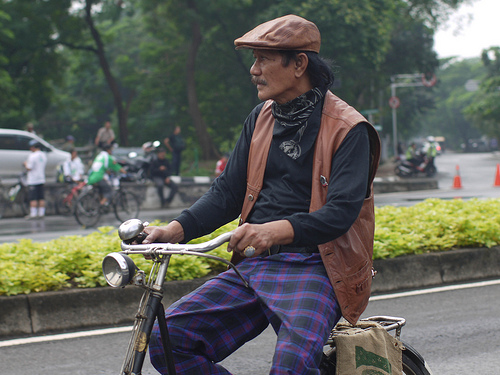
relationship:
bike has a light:
[89, 228, 417, 373] [101, 252, 135, 291]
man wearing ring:
[132, 10, 394, 374] [244, 242, 256, 257]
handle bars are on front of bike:
[116, 217, 241, 260] [89, 228, 417, 373]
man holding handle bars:
[132, 10, 394, 374] [116, 217, 241, 260]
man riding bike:
[132, 10, 394, 374] [89, 228, 417, 373]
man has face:
[132, 10, 394, 374] [246, 49, 280, 98]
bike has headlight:
[89, 228, 417, 373] [94, 251, 144, 290]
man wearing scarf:
[132, 10, 394, 374] [265, 83, 322, 162]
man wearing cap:
[132, 10, 394, 374] [236, 18, 320, 57]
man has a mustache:
[132, 10, 394, 374] [248, 77, 269, 88]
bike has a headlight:
[89, 228, 417, 373] [94, 251, 144, 290]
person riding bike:
[90, 139, 126, 204] [30, 133, 93, 175]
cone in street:
[447, 158, 464, 191] [421, 136, 500, 206]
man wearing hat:
[132, 10, 394, 374] [230, 10, 333, 58]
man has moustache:
[132, 10, 394, 374] [248, 71, 270, 86]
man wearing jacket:
[132, 10, 394, 374] [210, 98, 390, 333]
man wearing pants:
[132, 10, 394, 374] [150, 247, 351, 374]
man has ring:
[132, 10, 394, 374] [244, 242, 256, 257]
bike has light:
[89, 228, 417, 373] [101, 252, 135, 291]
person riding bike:
[90, 139, 126, 204] [89, 228, 417, 373]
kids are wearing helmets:
[18, 130, 196, 218] [27, 138, 173, 161]